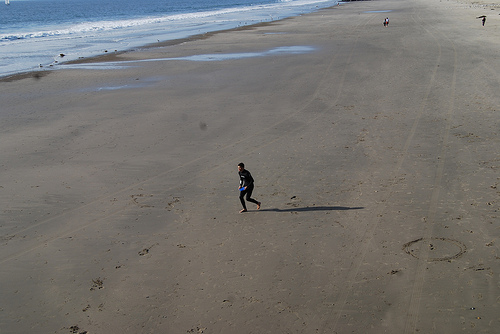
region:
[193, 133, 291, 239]
man on the sand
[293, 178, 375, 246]
shadow on the ground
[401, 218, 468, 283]
circle in the sand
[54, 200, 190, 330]
footprints in the sand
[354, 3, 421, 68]
people in the background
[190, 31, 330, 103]
water in the sand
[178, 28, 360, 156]
beach next to the water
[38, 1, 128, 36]
water next to the beach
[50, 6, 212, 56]
white wave in the water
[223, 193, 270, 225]
legs of the man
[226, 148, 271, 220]
adult male human in wet suit on beach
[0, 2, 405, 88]
ocean waves crashing onto beach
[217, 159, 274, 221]
man playing with flying disc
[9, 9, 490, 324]
ocean front beach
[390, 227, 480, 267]
circular track on beach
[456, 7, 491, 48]
bird flying across beach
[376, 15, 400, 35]
couple walking along beach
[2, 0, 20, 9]
boat in ocean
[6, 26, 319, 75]
temporary pool caused by ocean waves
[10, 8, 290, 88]
row of birds alongside ocean's edge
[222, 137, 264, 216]
man running on smooth sand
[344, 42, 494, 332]
vehicle tracks on sand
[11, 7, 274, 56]
ocean to the left of man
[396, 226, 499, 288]
small dark circle in sand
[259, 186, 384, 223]
shadow cast of running man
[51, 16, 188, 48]
Waves crashing on sand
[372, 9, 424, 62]
small object on sand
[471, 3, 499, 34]
small bird flying over sand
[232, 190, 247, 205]
blue shorts on running man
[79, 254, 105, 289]
seaweed washed up on shore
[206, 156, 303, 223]
A man wearing a black wetsuit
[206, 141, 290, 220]
A man running on the beach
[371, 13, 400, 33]
People standing on a beach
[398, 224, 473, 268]
A circle drawn in the sand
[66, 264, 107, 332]
Foot prints on a beach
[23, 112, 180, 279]
A brown sandy ground surface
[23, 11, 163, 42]
White waves in the ocean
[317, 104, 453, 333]
Tire tracks in the sand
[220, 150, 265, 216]
A man carrying a blue frisbee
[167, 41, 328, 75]
A wet sandy area on a beach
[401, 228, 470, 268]
Circle in the sand.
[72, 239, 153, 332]
Tracks in the sand.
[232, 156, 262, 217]
Man playing frisbee on the beach.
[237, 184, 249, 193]
Blue frisbee in man's hands.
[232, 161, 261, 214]
Man is wearing black wetsuit.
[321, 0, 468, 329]
Tire tracks on the beach.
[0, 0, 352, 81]
Water beside the sand.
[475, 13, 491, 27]
Person walking on the beach.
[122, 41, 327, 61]
Puddles of water in the sand.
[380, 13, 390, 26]
People in the background.